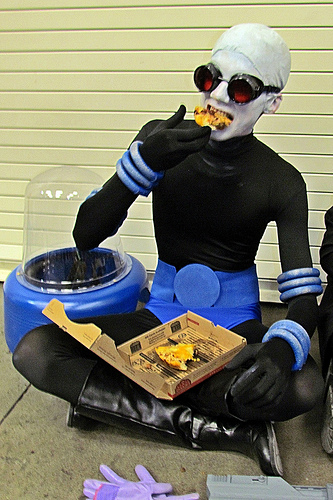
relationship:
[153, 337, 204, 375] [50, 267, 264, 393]
food in box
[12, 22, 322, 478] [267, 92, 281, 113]
girl has ear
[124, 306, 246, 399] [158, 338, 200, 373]
box has pizza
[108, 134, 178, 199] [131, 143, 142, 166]
bracelet on wrist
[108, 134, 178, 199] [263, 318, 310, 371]
bracelet on wrist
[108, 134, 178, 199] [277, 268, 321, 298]
bracelet on wrist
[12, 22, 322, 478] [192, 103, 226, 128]
girl eating food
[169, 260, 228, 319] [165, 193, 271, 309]
circle on stomach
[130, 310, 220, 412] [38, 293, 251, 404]
food in box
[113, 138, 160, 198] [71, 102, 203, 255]
bracelet on arm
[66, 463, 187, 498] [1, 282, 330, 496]
gloves on ground